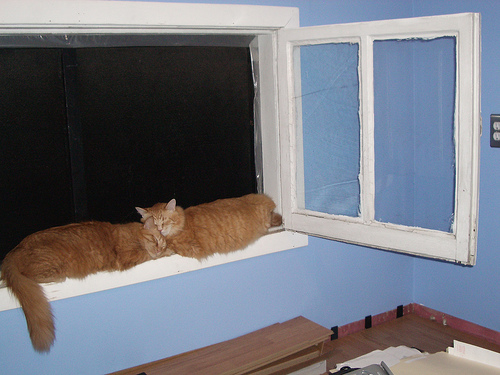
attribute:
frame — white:
[239, 16, 313, 208]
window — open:
[3, 38, 263, 238]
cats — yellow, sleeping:
[87, 214, 311, 253]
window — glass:
[299, 35, 364, 244]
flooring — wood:
[346, 310, 451, 353]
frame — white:
[0, 0, 480, 314]